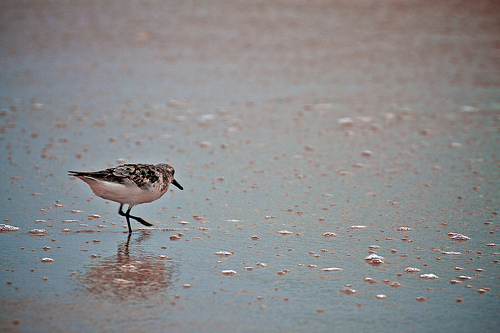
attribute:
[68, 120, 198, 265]
bird — standing, grey, feathers, colored, white, beak, eye, feet, reflection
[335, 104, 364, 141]
bubble — several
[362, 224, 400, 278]
object — these, small, white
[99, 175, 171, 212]
bottom — white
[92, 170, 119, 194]
feather — black, brown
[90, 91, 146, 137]
water — ripples, calm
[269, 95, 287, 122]
sand — wet